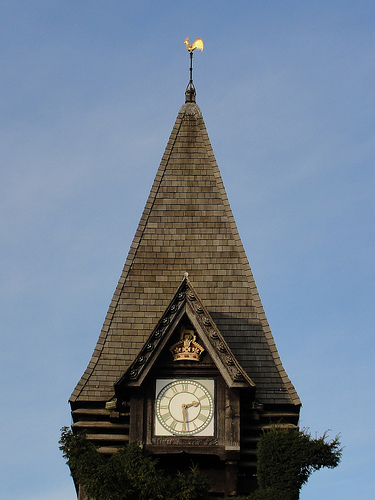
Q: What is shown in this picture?
A: A clock tower.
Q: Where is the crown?
A: Above the clock.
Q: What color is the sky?
A: Blue.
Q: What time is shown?
A: 2:30.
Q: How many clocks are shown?
A: 1.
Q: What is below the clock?
A: Trees.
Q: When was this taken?
A: The daytime.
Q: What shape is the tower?
A: A triangle.